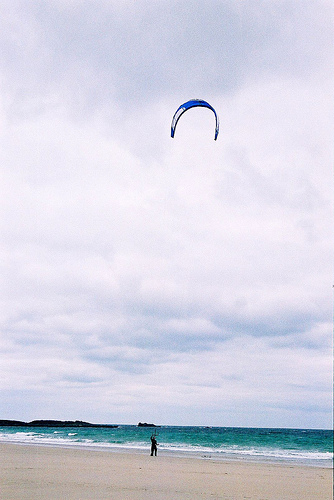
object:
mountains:
[0, 418, 156, 427]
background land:
[139, 422, 155, 429]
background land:
[1, 416, 118, 426]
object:
[170, 99, 220, 143]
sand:
[0, 440, 334, 498]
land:
[1, 440, 333, 497]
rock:
[136, 421, 158, 426]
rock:
[0, 418, 120, 428]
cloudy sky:
[1, 1, 333, 429]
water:
[1, 421, 333, 471]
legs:
[151, 447, 154, 455]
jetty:
[0, 418, 162, 428]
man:
[150, 433, 160, 456]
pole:
[182, 460, 280, 496]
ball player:
[199, 466, 282, 492]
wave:
[1, 430, 332, 460]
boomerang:
[172, 101, 218, 140]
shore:
[2, 439, 331, 497]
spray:
[2, 434, 333, 460]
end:
[0, 432, 20, 448]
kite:
[172, 99, 219, 142]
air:
[51, 40, 161, 302]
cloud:
[93, 338, 150, 379]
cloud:
[217, 298, 298, 335]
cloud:
[155, 314, 225, 342]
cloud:
[19, 250, 123, 305]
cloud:
[183, 369, 223, 392]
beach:
[0, 437, 326, 499]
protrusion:
[136, 420, 163, 429]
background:
[1, 321, 327, 433]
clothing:
[150, 435, 156, 457]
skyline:
[3, 404, 327, 439]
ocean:
[1, 423, 332, 461]